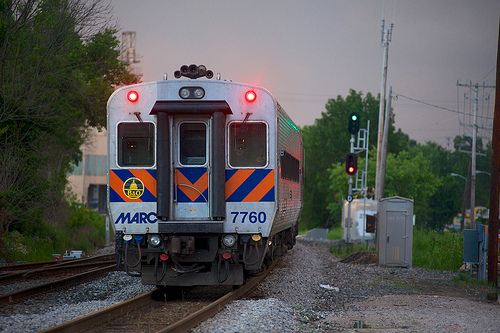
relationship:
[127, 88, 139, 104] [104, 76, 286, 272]
red lights on train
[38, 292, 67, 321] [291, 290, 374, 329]
gravel on ground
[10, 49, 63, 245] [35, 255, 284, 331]
trees next to train track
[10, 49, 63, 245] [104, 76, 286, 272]
trees next to train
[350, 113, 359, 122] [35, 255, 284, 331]
green light next to train track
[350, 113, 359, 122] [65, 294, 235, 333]
green light next to train track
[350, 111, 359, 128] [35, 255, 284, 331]
green light next to train track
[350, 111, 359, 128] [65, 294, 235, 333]
green light next to train track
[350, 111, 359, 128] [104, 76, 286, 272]
green light next to train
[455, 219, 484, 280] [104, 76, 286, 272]
electrical box next to train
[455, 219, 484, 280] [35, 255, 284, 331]
electrical box next to train track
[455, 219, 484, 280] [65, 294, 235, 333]
electrical box next to train track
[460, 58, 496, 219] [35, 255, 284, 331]
phone lines next to train track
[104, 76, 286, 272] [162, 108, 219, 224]
train has door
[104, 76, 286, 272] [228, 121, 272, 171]
train has windows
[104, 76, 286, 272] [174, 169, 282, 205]
train has stripes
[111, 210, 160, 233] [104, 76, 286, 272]
marc on train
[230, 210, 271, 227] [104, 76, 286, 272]
numbers on back of train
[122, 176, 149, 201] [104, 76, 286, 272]
logo on train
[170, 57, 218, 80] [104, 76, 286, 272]
horn on top of train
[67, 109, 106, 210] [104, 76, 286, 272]
building next to train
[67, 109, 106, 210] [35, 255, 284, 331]
building next to train track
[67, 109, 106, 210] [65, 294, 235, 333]
building next to train track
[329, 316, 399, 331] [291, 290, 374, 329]
water on ground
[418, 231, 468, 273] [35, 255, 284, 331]
long grass next to train track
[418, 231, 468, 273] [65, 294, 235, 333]
long grass next to train track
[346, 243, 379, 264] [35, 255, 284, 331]
pile of dirt next to train track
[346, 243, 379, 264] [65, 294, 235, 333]
pile of dirt next to train track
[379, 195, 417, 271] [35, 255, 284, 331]
small house next to train track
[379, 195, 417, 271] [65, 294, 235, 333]
small house next to train track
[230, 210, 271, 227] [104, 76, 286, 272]
7760 on back of train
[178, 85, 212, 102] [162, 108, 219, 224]
lights above door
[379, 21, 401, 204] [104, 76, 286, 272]
pole next to train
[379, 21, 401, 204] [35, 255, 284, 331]
pole next to train track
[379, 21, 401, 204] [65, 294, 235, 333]
pole next to train track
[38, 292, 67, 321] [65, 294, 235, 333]
gravel between train track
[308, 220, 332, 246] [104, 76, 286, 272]
road in front of train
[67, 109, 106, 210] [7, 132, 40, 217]
building to left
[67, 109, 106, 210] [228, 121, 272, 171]
building with windows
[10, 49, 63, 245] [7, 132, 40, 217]
trees to left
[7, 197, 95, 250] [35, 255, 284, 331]
bushes next to train track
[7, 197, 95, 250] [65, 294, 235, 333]
bushes next to train track